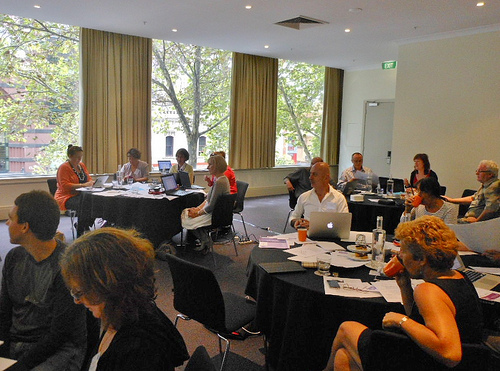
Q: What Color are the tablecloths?
A: Black.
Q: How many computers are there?
A: Six.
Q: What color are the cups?
A: Red.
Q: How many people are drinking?
A: Two.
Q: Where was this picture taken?
A: At a business meeting.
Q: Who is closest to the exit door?
A: Man holding paper.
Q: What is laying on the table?
A: Paper.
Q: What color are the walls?
A: White.